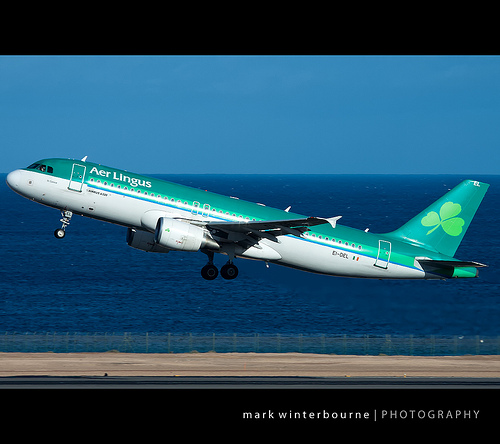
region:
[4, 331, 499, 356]
Short fence dividing runway from water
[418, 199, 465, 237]
Light green shamrock on tail of plane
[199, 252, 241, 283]
Rear wheels are down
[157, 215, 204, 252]
Left engine of plane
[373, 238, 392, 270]
Rear door of airplane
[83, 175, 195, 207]
Section of passenger windows of plane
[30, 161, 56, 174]
Pilot plane windows of plane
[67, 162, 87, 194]
Front door of airplane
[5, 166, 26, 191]
Nose of airplane is white and rounded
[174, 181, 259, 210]
Top of airplane is green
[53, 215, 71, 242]
the landing gear of a plane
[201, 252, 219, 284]
the landing gear of a plane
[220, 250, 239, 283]
the landing gear of a plane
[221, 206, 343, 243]
a wing of a plane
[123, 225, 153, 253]
an engine of a plane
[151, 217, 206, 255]
an engine of a plane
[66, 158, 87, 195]
a door of a plane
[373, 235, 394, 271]
a door of a plane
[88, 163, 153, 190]
white lettering on a plane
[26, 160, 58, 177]
the front window of a plane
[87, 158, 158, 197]
The words "Aer Lingus" on an airplane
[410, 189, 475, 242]
A 3-leaf clover design on an airplane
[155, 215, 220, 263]
The left engine of a plane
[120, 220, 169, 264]
The right engine of a plane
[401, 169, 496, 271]
The tail fin of an airplane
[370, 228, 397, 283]
The backdoor of an airplane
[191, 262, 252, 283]
the landing wheels of an airplane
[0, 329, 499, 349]
Fencing across an airplane strip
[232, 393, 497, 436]
The name of the photographer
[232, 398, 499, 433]
A watermark on the picture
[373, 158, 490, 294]
Shamrock on tail of airplane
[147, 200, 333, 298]
Turbine engine on airplane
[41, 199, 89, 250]
Front airplane landing gear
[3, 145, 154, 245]
Cockpit on commercial airplane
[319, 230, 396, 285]
Irish Logo on belly of airplane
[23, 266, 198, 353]
Fence around airport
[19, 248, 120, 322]
Ocean water on sunny day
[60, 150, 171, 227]
Aer Lingus logo on airplane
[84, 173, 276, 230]
Passenger windows on front of airplane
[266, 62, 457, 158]
Blue sky in daylight time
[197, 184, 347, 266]
the left wing on a plane.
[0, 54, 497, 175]
a crystal clear blue sky.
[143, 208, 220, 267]
a large jet engine.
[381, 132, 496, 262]
A tail wing on a jet.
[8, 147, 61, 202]
the front of a jet.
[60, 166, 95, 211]
the door on the side of a jet.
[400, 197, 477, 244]
A clover on a jet.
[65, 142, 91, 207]
a door on a plane.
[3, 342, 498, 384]
A runway near a jet.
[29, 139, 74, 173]
windows on a cockpit.